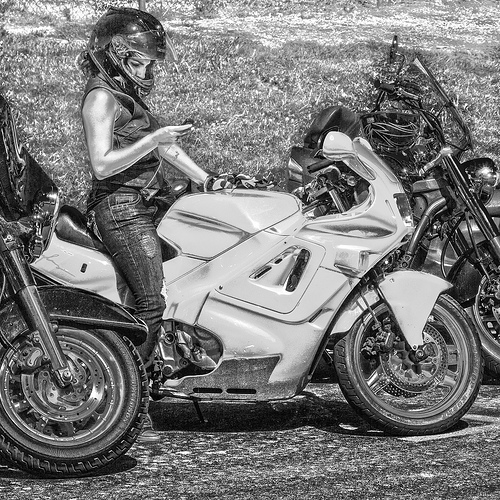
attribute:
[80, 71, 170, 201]
jacket — sleeveless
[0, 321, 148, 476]
tire — back tire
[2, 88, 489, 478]
motorbike — front part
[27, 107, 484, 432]
motorbike — right side of the body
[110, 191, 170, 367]
jeans — denim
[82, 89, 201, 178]
arm — womens arm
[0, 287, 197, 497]
wheel — front wheel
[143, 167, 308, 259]
tank — gas tank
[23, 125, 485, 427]
bike — side view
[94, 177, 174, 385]
leg — woman's leg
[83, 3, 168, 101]
head — woman's head, looking down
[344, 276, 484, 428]
tire — front tire, round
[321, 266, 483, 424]
tire — round